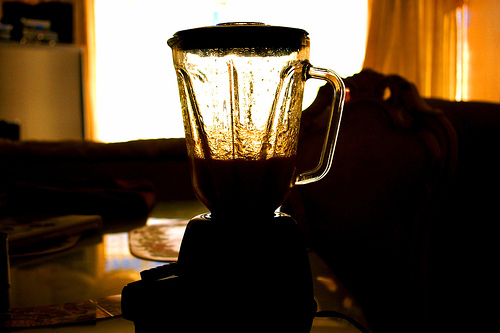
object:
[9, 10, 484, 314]
photo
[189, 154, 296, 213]
liquid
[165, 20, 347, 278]
kitchen appliance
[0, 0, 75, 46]
books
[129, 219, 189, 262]
stuff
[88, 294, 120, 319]
stuff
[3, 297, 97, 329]
stuff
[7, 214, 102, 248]
stuff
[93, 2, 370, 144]
sunny window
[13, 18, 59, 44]
things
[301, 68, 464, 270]
man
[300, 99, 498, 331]
sofa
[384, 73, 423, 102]
hand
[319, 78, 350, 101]
hand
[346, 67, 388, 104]
head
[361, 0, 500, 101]
curtain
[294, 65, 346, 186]
handle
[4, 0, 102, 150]
wall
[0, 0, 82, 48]
shelf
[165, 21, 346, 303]
blender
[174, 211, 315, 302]
appliance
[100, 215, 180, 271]
reflection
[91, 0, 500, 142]
window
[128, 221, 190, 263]
mat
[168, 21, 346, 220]
pitcher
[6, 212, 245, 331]
table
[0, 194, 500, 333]
counter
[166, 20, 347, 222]
glass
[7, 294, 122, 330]
paperwork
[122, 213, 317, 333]
stand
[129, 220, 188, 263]
napkins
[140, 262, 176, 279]
buttons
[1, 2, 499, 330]
sunlight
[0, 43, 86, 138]
shelf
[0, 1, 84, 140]
wall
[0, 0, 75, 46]
cds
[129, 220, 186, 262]
part